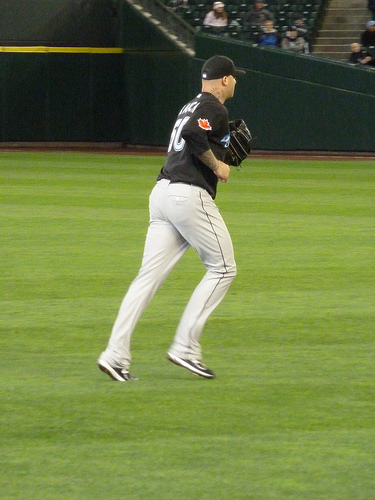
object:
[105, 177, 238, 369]
pants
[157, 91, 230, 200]
t shirt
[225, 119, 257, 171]
glove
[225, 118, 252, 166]
man's hand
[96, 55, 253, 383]
man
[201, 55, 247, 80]
hat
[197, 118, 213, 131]
tag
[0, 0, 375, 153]
wall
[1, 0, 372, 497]
stadium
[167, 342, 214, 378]
right shoe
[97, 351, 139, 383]
left shoe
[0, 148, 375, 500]
grass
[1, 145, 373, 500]
playing field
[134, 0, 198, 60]
stairs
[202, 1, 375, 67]
people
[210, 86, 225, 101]
tattoo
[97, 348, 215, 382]
cleats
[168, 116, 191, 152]
numbers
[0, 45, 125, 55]
line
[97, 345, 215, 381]
feet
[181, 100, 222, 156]
sleeve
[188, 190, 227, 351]
stripe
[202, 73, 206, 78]
logo